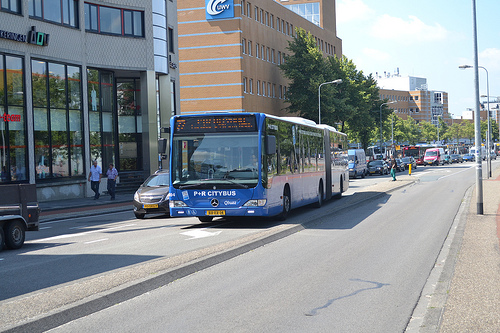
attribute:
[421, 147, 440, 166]
van — pink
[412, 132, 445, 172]
van — red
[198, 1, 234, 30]
sign — blue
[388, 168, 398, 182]
pants — green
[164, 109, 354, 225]
bus — blue, multi-color, large, one, car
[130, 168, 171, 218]
car — black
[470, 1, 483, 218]
pole — gray, metal, electrical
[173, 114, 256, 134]
destination sign — electronic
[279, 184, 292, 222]
tire — black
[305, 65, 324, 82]
leaves — green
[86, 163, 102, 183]
shirt — white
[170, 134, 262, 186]
windshield — big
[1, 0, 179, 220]
building — tall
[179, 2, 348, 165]
building — tall, brown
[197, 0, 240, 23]
sign — blue, white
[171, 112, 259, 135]
sign — electric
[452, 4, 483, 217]
poles — tall, gray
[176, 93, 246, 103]
blue line — long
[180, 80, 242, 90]
blue line — long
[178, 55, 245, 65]
blue line — long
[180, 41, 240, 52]
blue line — long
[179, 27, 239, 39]
blue line — long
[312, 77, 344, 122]
light post — large, silver and white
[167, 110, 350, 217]
bus — large, blue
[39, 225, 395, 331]
median — concrete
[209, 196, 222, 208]
logo — Mercedes Benz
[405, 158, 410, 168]
pole — yellow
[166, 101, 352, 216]
bus — blue, public, service bus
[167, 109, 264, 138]
sign — electronic, destination sign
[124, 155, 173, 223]
car — grey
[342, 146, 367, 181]
van — blue, parked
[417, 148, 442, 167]
van — red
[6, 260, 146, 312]
median — raised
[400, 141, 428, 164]
bus — red, public, service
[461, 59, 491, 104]
light — overhead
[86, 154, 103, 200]
person — walking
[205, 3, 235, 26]
sign — a logo, a business sign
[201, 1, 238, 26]
sign — blue, white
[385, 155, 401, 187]
man — crossing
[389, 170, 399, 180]
pants — green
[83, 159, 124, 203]
men — walking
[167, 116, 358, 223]
bus — blue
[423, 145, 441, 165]
van — red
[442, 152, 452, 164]
car — green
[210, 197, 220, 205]
logo — chrome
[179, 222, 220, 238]
arrow — white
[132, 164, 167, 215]
car — black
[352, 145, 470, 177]
line — long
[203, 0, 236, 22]
sign — blue